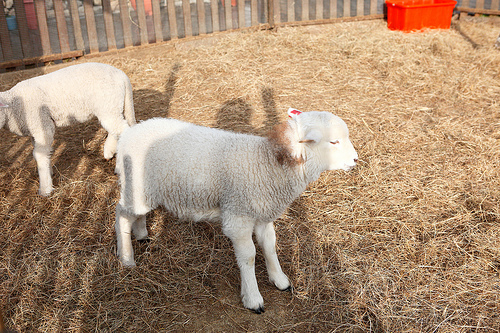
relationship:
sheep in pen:
[1, 60, 137, 196] [5, 2, 490, 294]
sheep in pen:
[115, 90, 364, 263] [8, 1, 493, 327]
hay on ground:
[0, 12, 499, 332] [3, 295, 498, 329]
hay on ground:
[0, 12, 499, 332] [1, 15, 493, 332]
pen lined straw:
[30, 14, 495, 311] [2, 7, 495, 329]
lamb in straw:
[105, 100, 370, 321] [2, 7, 495, 329]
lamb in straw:
[2, 52, 142, 202] [2, 7, 495, 329]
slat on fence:
[250, 0, 260, 27] [0, 0, 499, 74]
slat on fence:
[181, 1, 193, 40] [0, 0, 499, 74]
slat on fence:
[99, 0, 116, 47] [0, 0, 499, 74]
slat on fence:
[341, 0, 352, 20] [0, 0, 499, 74]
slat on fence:
[82, 2, 97, 55] [0, 0, 499, 74]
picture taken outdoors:
[7, 5, 497, 324] [6, 1, 497, 323]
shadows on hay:
[1, 64, 336, 331] [1, 57, 378, 321]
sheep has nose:
[107, 100, 367, 314] [350, 155, 363, 163]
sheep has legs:
[107, 100, 367, 314] [103, 179, 298, 323]